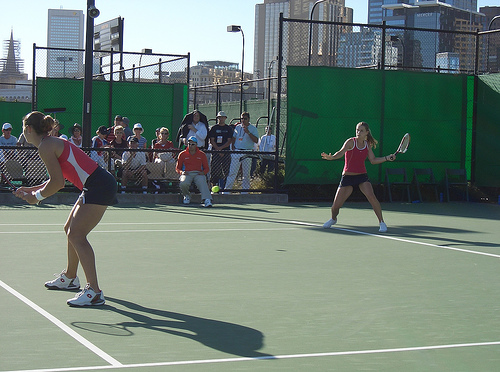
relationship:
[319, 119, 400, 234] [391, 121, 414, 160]
player holding racket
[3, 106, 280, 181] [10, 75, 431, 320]
spectators watching game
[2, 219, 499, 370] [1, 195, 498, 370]
white lines on court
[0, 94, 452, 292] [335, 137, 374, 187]
players in uniform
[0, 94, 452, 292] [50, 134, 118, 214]
players in uniform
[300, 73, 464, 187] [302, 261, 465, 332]
mesh blocks sun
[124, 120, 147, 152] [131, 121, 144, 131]
woman with hat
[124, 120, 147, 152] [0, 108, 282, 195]
woman in audience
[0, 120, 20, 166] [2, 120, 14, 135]
woman with cap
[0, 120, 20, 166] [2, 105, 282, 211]
woman in audience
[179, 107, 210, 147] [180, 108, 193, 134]
man with shirt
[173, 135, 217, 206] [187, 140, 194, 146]
coach wearing sunglasses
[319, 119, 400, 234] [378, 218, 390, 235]
player with shoe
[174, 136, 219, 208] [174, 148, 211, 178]
man wearing pull-over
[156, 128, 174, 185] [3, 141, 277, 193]
spectator behind fence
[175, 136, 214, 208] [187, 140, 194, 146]
man in sunglasses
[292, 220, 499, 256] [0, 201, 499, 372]
white lines on court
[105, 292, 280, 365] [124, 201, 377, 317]
shadow on court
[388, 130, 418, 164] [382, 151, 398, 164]
racket in hand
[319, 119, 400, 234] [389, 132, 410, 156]
player with racket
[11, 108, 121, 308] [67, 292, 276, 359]
players has shadow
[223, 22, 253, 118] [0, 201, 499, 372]
pole near court